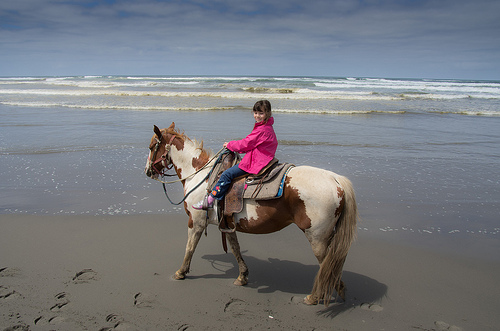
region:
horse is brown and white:
[115, 94, 392, 329]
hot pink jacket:
[215, 117, 289, 177]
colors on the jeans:
[206, 171, 233, 197]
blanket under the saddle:
[239, 160, 299, 209]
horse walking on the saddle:
[120, 106, 388, 322]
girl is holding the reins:
[206, 132, 248, 162]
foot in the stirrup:
[194, 184, 225, 215]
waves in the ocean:
[110, 63, 448, 107]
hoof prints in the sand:
[7, 243, 166, 329]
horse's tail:
[305, 173, 365, 322]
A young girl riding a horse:
[192, 99, 277, 209]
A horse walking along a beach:
[145, 121, 355, 304]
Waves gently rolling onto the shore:
[3, 77, 498, 116]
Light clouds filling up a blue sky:
[1, 0, 498, 82]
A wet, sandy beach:
[0, 212, 498, 329]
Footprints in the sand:
[0, 266, 247, 328]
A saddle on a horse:
[208, 147, 293, 199]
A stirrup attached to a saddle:
[218, 212, 238, 232]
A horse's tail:
[313, 176, 357, 305]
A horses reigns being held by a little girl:
[148, 137, 228, 204]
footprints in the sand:
[5, 282, 136, 327]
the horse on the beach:
[115, 90, 401, 295]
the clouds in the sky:
[5, 5, 215, 55]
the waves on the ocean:
[5, 66, 480, 96]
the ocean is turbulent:
[0, 66, 495, 106]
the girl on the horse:
[179, 99, 279, 216]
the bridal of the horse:
[141, 133, 176, 172]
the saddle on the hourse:
[215, 152, 295, 196]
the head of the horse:
[120, 126, 196, 181]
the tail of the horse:
[300, 183, 380, 308]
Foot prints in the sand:
[2, 271, 485, 329]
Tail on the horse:
[313, 174, 360, 325]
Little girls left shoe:
[189, 194, 210, 212]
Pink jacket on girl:
[230, 124, 280, 169]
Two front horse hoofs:
[170, 262, 255, 287]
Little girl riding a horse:
[145, 96, 360, 303]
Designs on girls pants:
[205, 181, 225, 199]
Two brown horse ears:
[150, 120, 185, 137]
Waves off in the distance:
[2, 69, 499, 110]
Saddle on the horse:
[219, 154, 292, 204]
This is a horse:
[131, 90, 391, 320]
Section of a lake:
[20, 113, 110, 225]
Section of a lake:
[381, 135, 478, 290]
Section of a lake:
[340, 75, 491, 157]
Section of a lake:
[307, 64, 490, 114]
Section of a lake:
[174, 75, 256, 123]